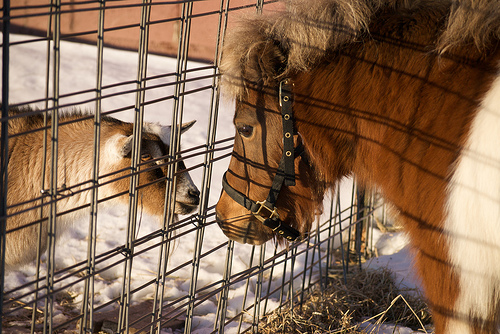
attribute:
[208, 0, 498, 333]
pony — brown, white